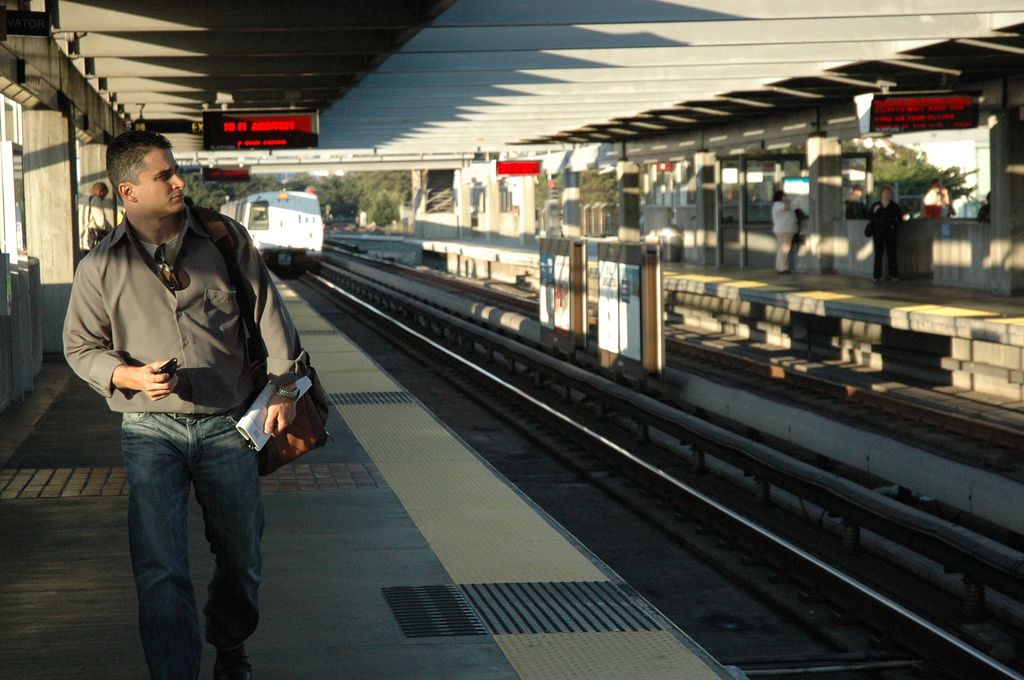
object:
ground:
[0, 322, 703, 680]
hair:
[102, 127, 173, 189]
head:
[97, 123, 192, 224]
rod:
[628, 452, 895, 609]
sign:
[191, 100, 327, 155]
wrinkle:
[167, 281, 234, 360]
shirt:
[47, 204, 321, 429]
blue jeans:
[107, 404, 284, 677]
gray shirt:
[55, 200, 314, 420]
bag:
[191, 202, 338, 476]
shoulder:
[180, 191, 277, 301]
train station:
[0, 0, 1021, 680]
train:
[209, 184, 334, 272]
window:
[242, 197, 274, 233]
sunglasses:
[137, 242, 190, 293]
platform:
[588, 230, 1024, 413]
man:
[52, 124, 321, 680]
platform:
[0, 237, 729, 680]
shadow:
[804, 355, 869, 383]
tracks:
[731, 352, 1024, 440]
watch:
[272, 385, 306, 401]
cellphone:
[145, 353, 186, 396]